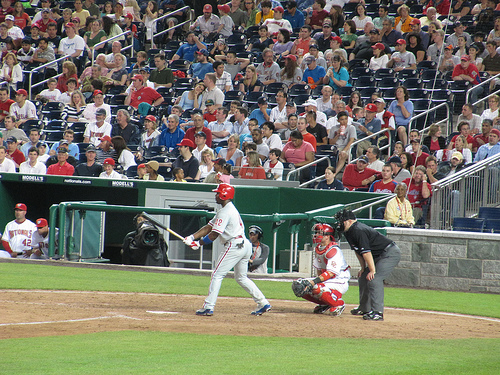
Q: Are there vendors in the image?
A: No, there are no vendors.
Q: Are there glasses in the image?
A: No, there are no glasses.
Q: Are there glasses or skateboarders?
A: No, there are no glasses or skateboarders.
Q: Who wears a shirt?
A: The man wears a shirt.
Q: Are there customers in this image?
A: No, there are no customers.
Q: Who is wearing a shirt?
A: The man is wearing a shirt.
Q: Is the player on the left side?
A: Yes, the player is on the left of the image.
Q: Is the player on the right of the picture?
A: No, the player is on the left of the image.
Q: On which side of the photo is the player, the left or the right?
A: The player is on the left of the image.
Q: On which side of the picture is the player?
A: The player is on the left of the image.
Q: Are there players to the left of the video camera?
A: Yes, there is a player to the left of the video camera.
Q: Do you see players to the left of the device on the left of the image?
A: Yes, there is a player to the left of the video camera.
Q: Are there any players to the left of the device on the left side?
A: Yes, there is a player to the left of the video camera.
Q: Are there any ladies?
A: No, there are no ladies.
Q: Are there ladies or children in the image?
A: No, there are no ladies or children.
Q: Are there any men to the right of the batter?
A: Yes, there is a man to the right of the batter.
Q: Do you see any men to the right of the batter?
A: Yes, there is a man to the right of the batter.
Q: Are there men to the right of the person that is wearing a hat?
A: Yes, there is a man to the right of the batter.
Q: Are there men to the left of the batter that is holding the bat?
A: No, the man is to the right of the batter.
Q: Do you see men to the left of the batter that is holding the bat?
A: No, the man is to the right of the batter.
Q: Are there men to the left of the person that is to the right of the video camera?
A: No, the man is to the right of the batter.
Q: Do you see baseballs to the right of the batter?
A: No, there is a man to the right of the batter.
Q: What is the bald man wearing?
A: The man is wearing a shirt.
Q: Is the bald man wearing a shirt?
A: Yes, the man is wearing a shirt.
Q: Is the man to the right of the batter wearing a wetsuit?
A: No, the man is wearing a shirt.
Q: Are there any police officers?
A: No, there are no police officers.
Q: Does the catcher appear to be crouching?
A: Yes, the catcher is crouching.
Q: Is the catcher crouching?
A: Yes, the catcher is crouching.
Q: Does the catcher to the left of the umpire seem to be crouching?
A: Yes, the catcher is crouching.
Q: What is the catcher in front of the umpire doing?
A: The catcher is crouching.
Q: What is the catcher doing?
A: The catcher is crouching.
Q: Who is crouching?
A: The catcher is crouching.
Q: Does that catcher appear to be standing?
A: No, the catcher is crouching.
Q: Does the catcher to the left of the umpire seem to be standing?
A: No, the catcher is crouching.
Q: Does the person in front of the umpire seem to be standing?
A: No, the catcher is crouching.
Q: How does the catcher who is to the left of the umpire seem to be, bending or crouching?
A: The catcher is crouching.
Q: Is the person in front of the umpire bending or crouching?
A: The catcher is crouching.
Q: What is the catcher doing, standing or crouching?
A: The catcher is crouching.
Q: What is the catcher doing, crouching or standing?
A: The catcher is crouching.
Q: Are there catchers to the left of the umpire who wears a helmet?
A: Yes, there is a catcher to the left of the umpire.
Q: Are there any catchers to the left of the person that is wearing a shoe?
A: Yes, there is a catcher to the left of the umpire.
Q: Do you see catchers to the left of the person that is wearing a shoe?
A: Yes, there is a catcher to the left of the umpire.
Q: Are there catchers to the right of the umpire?
A: No, the catcher is to the left of the umpire.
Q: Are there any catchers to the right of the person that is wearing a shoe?
A: No, the catcher is to the left of the umpire.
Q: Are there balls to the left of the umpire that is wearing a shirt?
A: No, there is a catcher to the left of the umpire.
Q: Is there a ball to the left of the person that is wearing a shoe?
A: No, there is a catcher to the left of the umpire.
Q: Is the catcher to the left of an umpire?
A: Yes, the catcher is to the left of an umpire.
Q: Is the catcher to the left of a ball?
A: No, the catcher is to the left of an umpire.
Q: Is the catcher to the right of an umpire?
A: No, the catcher is to the left of an umpire.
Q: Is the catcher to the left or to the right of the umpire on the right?
A: The catcher is to the left of the umpire.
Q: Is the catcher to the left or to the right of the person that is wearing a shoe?
A: The catcher is to the left of the umpire.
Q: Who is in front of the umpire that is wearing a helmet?
A: The catcher is in front of the umpire.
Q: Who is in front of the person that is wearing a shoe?
A: The catcher is in front of the umpire.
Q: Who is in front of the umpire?
A: The catcher is in front of the umpire.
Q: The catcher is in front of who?
A: The catcher is in front of the umpire.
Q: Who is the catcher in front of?
A: The catcher is in front of the umpire.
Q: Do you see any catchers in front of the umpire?
A: Yes, there is a catcher in front of the umpire.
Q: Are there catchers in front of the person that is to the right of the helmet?
A: Yes, there is a catcher in front of the umpire.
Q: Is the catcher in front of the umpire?
A: Yes, the catcher is in front of the umpire.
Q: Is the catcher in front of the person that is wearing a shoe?
A: Yes, the catcher is in front of the umpire.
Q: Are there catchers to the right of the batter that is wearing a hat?
A: Yes, there is a catcher to the right of the batter.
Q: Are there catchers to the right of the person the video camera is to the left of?
A: Yes, there is a catcher to the right of the batter.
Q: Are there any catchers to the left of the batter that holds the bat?
A: No, the catcher is to the right of the batter.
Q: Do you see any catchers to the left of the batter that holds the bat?
A: No, the catcher is to the right of the batter.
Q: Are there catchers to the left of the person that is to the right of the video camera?
A: No, the catcher is to the right of the batter.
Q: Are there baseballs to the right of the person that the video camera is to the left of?
A: No, there is a catcher to the right of the batter.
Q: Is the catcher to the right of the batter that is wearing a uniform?
A: Yes, the catcher is to the right of the batter.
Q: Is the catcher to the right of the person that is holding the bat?
A: Yes, the catcher is to the right of the batter.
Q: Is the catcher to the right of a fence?
A: No, the catcher is to the right of the batter.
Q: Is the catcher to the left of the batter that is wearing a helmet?
A: No, the catcher is to the right of the batter.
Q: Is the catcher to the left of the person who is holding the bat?
A: No, the catcher is to the right of the batter.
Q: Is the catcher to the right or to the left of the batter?
A: The catcher is to the right of the batter.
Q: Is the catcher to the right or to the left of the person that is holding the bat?
A: The catcher is to the right of the batter.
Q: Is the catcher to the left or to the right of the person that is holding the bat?
A: The catcher is to the right of the batter.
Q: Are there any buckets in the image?
A: No, there are no buckets.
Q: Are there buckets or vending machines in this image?
A: No, there are no buckets or vending machines.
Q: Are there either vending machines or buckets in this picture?
A: No, there are no buckets or vending machines.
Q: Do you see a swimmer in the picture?
A: No, there are no swimmers.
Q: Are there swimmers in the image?
A: No, there are no swimmers.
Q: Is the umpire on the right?
A: Yes, the umpire is on the right of the image.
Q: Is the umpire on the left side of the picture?
A: No, the umpire is on the right of the image.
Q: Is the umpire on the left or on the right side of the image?
A: The umpire is on the right of the image.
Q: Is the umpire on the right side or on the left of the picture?
A: The umpire is on the right of the image.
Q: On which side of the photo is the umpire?
A: The umpire is on the right of the image.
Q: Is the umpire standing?
A: Yes, the umpire is standing.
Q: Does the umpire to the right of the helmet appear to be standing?
A: Yes, the umpire is standing.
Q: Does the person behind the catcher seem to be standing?
A: Yes, the umpire is standing.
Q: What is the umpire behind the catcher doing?
A: The umpire is standing.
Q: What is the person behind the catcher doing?
A: The umpire is standing.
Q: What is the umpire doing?
A: The umpire is standing.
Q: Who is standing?
A: The umpire is standing.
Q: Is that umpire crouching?
A: No, the umpire is standing.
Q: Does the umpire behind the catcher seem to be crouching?
A: No, the umpire is standing.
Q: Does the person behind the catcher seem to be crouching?
A: No, the umpire is standing.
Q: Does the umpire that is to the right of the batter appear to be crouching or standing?
A: The umpire is standing.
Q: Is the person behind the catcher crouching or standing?
A: The umpire is standing.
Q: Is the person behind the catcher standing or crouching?
A: The umpire is standing.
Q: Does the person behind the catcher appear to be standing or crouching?
A: The umpire is standing.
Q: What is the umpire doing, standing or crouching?
A: The umpire is standing.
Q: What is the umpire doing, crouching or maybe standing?
A: The umpire is standing.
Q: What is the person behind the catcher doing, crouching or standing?
A: The umpire is standing.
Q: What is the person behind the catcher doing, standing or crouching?
A: The umpire is standing.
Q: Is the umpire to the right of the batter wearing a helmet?
A: Yes, the umpire is wearing a helmet.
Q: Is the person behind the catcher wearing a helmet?
A: Yes, the umpire is wearing a helmet.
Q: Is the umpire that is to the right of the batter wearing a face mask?
A: No, the umpire is wearing a helmet.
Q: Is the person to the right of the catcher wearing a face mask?
A: No, the umpire is wearing a helmet.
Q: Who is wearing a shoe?
A: The umpire is wearing a shoe.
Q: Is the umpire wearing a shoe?
A: Yes, the umpire is wearing a shoe.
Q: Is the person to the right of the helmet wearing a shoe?
A: Yes, the umpire is wearing a shoe.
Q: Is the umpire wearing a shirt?
A: Yes, the umpire is wearing a shirt.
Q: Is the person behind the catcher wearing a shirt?
A: Yes, the umpire is wearing a shirt.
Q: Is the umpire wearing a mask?
A: No, the umpire is wearing a shirt.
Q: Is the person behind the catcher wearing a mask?
A: No, the umpire is wearing a shirt.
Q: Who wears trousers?
A: The umpire wears trousers.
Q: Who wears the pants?
A: The umpire wears trousers.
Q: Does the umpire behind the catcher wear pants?
A: Yes, the umpire wears pants.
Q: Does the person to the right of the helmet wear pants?
A: Yes, the umpire wears pants.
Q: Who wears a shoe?
A: The umpire wears a shoe.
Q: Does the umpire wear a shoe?
A: Yes, the umpire wears a shoe.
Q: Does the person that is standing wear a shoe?
A: Yes, the umpire wears a shoe.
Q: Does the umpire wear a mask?
A: No, the umpire wears a shoe.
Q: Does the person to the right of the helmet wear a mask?
A: No, the umpire wears a shoe.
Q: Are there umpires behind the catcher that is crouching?
A: Yes, there is an umpire behind the catcher.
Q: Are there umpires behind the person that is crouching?
A: Yes, there is an umpire behind the catcher.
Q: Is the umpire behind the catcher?
A: Yes, the umpire is behind the catcher.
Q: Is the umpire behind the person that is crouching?
A: Yes, the umpire is behind the catcher.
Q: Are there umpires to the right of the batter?
A: Yes, there is an umpire to the right of the batter.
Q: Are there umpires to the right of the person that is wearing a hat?
A: Yes, there is an umpire to the right of the batter.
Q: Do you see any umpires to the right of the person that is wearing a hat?
A: Yes, there is an umpire to the right of the batter.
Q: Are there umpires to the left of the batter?
A: No, the umpire is to the right of the batter.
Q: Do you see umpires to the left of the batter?
A: No, the umpire is to the right of the batter.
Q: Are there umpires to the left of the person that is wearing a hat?
A: No, the umpire is to the right of the batter.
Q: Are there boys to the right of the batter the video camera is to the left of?
A: No, there is an umpire to the right of the batter.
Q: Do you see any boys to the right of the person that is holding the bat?
A: No, there is an umpire to the right of the batter.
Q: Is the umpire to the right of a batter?
A: Yes, the umpire is to the right of a batter.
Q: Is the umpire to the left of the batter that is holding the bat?
A: No, the umpire is to the right of the batter.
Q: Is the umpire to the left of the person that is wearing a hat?
A: No, the umpire is to the right of the batter.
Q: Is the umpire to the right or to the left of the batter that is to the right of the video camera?
A: The umpire is to the right of the batter.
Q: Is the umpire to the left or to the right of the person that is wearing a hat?
A: The umpire is to the right of the batter.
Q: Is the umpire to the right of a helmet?
A: Yes, the umpire is to the right of a helmet.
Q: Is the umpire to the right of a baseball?
A: No, the umpire is to the right of a helmet.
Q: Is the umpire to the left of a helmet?
A: No, the umpire is to the right of a helmet.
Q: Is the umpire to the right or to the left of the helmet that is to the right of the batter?
A: The umpire is to the right of the helmet.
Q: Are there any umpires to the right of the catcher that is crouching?
A: Yes, there is an umpire to the right of the catcher.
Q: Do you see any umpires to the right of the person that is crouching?
A: Yes, there is an umpire to the right of the catcher.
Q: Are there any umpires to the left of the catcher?
A: No, the umpire is to the right of the catcher.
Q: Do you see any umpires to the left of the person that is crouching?
A: No, the umpire is to the right of the catcher.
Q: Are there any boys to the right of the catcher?
A: No, there is an umpire to the right of the catcher.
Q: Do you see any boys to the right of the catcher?
A: No, there is an umpire to the right of the catcher.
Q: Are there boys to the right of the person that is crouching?
A: No, there is an umpire to the right of the catcher.